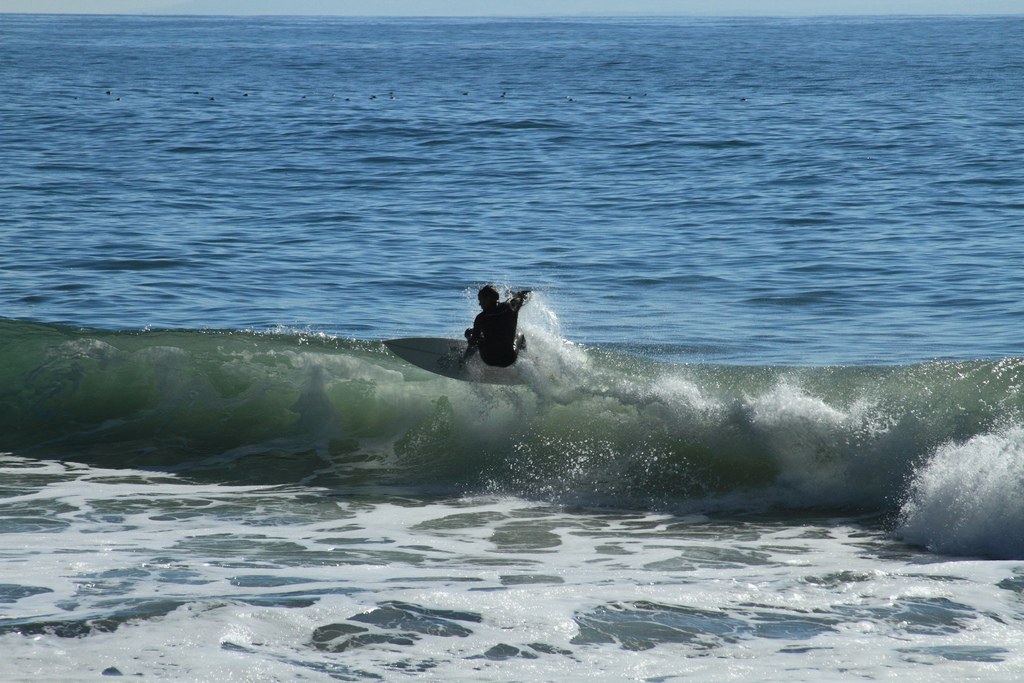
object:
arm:
[462, 317, 482, 362]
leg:
[514, 329, 528, 361]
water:
[572, 596, 739, 647]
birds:
[299, 41, 835, 130]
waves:
[0, 105, 1024, 349]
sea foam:
[0, 508, 1021, 679]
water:
[9, 19, 1024, 361]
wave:
[0, 295, 1019, 562]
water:
[580, 350, 879, 525]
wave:
[649, 365, 1024, 540]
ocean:
[0, 7, 1022, 233]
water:
[0, 0, 1024, 270]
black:
[466, 303, 524, 368]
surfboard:
[381, 337, 554, 385]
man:
[462, 284, 531, 368]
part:
[0, 454, 1021, 683]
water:
[0, 13, 1019, 681]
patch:
[644, 0, 872, 19]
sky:
[2, 0, 1024, 18]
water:
[17, 28, 1024, 265]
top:
[666, 381, 998, 446]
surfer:
[458, 285, 525, 368]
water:
[632, 299, 860, 502]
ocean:
[436, 381, 616, 487]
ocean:
[591, 80, 879, 447]